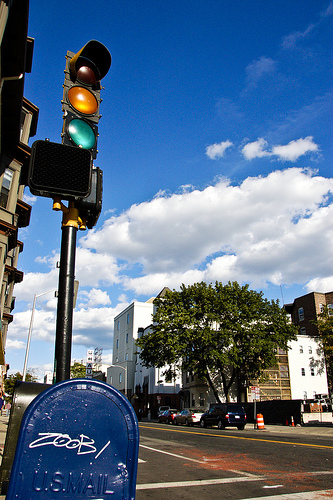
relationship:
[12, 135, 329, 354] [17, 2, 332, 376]
clouds in sky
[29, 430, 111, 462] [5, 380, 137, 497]
graffiti on post box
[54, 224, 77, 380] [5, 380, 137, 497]
pole behind post box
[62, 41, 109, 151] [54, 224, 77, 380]
light on pole